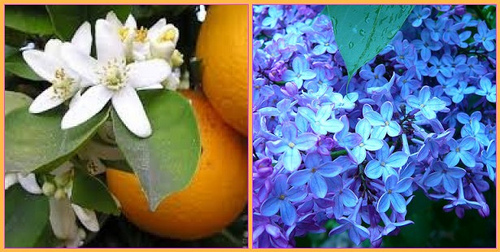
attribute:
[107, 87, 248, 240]
orange — dimpled, specked, round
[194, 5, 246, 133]
orange — specked, round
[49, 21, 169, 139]
flower — small, white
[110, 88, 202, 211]
leaf — brown, folded, green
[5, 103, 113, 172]
leaf — brown, side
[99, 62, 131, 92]
center — middle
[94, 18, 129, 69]
petal — white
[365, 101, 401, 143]
flower — purple, little, small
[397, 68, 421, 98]
flower — blue, purple, little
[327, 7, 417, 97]
leaf — pointed, green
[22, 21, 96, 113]
flower — white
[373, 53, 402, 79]
spot — dark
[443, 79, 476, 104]
flower — small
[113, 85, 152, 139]
petal — white